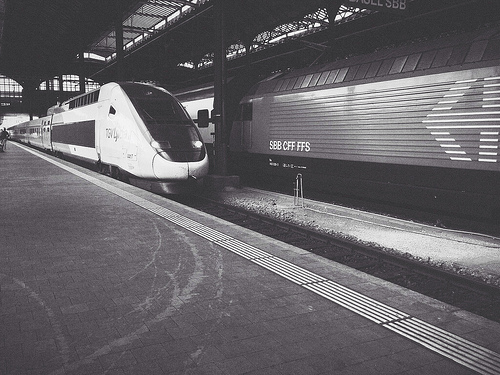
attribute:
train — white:
[80, 87, 180, 179]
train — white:
[14, 78, 219, 189]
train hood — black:
[120, 76, 210, 161]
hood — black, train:
[117, 74, 207, 166]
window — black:
[48, 119, 97, 151]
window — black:
[117, 77, 207, 162]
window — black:
[76, 92, 87, 143]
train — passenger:
[12, 71, 205, 184]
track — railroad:
[201, 189, 468, 306]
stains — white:
[2, 222, 236, 372]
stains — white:
[12, 214, 252, 372]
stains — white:
[15, 218, 240, 368]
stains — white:
[8, 198, 275, 372]